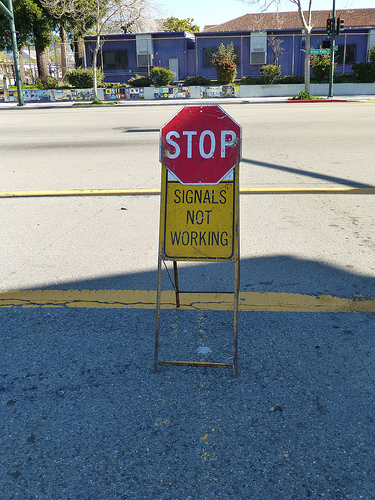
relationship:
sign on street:
[134, 114, 265, 360] [261, 159, 331, 271]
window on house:
[84, 49, 136, 72] [87, 30, 374, 87]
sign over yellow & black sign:
[167, 89, 229, 171] [165, 176, 238, 265]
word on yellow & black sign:
[171, 207, 229, 228] [165, 176, 238, 265]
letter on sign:
[163, 126, 193, 172] [134, 114, 265, 360]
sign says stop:
[134, 114, 265, 360] [165, 127, 260, 161]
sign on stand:
[134, 114, 265, 360] [141, 268, 255, 344]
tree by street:
[4, 3, 62, 87] [261, 159, 331, 271]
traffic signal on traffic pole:
[325, 22, 336, 40] [329, 55, 341, 99]